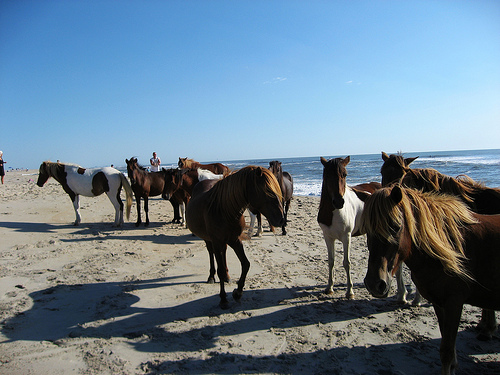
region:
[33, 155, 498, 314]
horses on the sand at a beach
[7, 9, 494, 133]
blue sky with no clouds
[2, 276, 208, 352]
shadows of horses in the sand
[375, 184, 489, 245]
blonde mane of horse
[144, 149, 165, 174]
male on the beach behind horses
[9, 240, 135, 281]
sand on the beach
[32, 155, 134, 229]
white and brown horse standing sideways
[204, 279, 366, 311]
hooves of horses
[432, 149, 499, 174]
wave of an ocean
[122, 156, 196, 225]
brown horse standing sideways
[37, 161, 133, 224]
A brown and white horse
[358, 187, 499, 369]
A brown horse with blonde mane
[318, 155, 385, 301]
A brown and white horse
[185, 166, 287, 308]
A brown horse with a brown mane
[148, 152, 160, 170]
A man in a white shirt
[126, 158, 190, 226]
A brown horse with a dark mane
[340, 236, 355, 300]
A horse's leg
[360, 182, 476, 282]
A blonde mane of a horse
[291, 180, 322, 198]
Ocean waves near a beach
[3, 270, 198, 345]
The shadow of a horse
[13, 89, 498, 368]
Picture of horses on a beach.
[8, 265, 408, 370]
Shadows of horses on the beach.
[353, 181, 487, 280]
Mane on horse in foreground.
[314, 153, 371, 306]
Brown and white horse on right side.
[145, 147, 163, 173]
Person behind horses in background.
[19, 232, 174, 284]
Tracks in the sand.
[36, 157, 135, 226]
Brown and white horse on the left.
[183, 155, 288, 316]
Brown horse in the middle.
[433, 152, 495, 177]
White caps on ocean waves.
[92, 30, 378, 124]
Clear, blue sky.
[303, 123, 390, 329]
horse is brown and white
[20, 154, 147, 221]
horse is brown and white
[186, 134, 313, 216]
horse is brown and white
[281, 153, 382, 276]
horse is brown and white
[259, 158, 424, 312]
horse is brown and white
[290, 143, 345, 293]
horse is brown and white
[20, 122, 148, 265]
horse is brown and white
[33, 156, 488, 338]
horses on sandy beach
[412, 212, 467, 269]
long flowing mane on horse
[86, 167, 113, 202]
brown spot on white body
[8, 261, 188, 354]
shadow of horse in sand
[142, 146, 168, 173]
person standing beyond horses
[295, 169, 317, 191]
white sea foam near shore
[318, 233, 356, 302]
white legs on horse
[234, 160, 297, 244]
horse looking toward water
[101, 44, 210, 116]
clear blue daytime sky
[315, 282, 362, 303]
hooves on white legs